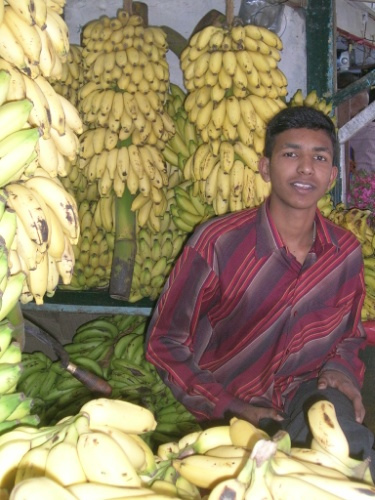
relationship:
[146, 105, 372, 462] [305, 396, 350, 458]
man selling fruit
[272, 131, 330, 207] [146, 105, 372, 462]
face on man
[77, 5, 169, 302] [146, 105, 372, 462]
bananas around man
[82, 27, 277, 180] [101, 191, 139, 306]
fruit bunches along trunk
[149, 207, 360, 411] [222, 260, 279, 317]
shirt has stripes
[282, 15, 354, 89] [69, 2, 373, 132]
wall on building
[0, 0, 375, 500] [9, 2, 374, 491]
wall on building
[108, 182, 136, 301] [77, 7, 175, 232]
pole with bananas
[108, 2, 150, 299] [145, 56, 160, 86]
beam of banana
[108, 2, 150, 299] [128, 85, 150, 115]
beam of banana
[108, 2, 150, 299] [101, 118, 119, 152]
beam of banana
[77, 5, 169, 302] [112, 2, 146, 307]
bananas on pole